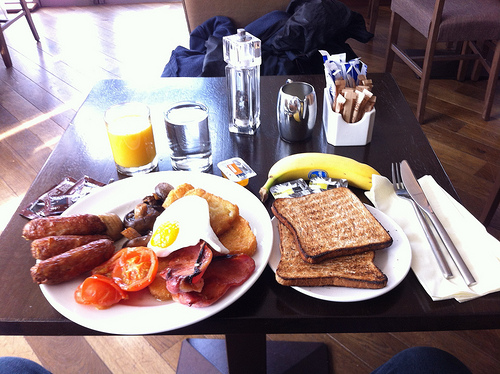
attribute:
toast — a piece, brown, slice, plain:
[271, 186, 393, 263]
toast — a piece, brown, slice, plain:
[276, 221, 389, 289]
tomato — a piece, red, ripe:
[76, 276, 129, 309]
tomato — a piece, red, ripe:
[91, 247, 157, 292]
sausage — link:
[23, 215, 108, 240]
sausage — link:
[32, 234, 109, 259]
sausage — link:
[31, 238, 115, 284]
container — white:
[322, 86, 375, 147]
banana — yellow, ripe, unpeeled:
[258, 152, 381, 204]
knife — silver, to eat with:
[401, 159, 478, 289]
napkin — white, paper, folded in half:
[364, 173, 499, 303]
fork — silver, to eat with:
[391, 162, 455, 281]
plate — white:
[268, 202, 413, 303]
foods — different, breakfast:
[22, 182, 258, 310]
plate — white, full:
[36, 170, 274, 336]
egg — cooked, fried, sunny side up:
[148, 195, 230, 259]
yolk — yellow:
[150, 221, 178, 249]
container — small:
[217, 156, 258, 187]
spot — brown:
[267, 174, 273, 179]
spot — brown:
[368, 179, 373, 186]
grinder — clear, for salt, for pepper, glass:
[223, 29, 263, 135]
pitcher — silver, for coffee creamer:
[276, 79, 318, 146]